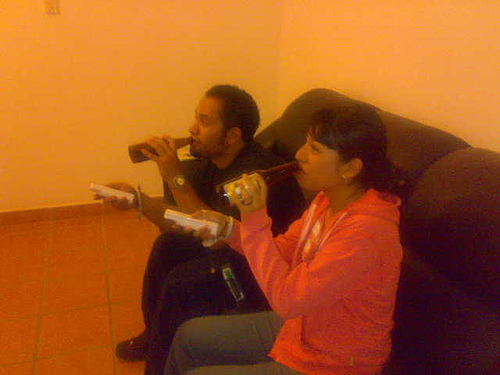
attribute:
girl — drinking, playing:
[169, 104, 407, 373]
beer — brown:
[217, 159, 299, 201]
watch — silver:
[166, 175, 191, 189]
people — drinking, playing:
[101, 87, 406, 371]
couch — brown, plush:
[179, 86, 497, 372]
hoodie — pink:
[243, 189, 398, 370]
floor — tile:
[0, 210, 158, 374]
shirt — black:
[198, 138, 304, 235]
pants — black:
[143, 235, 232, 343]